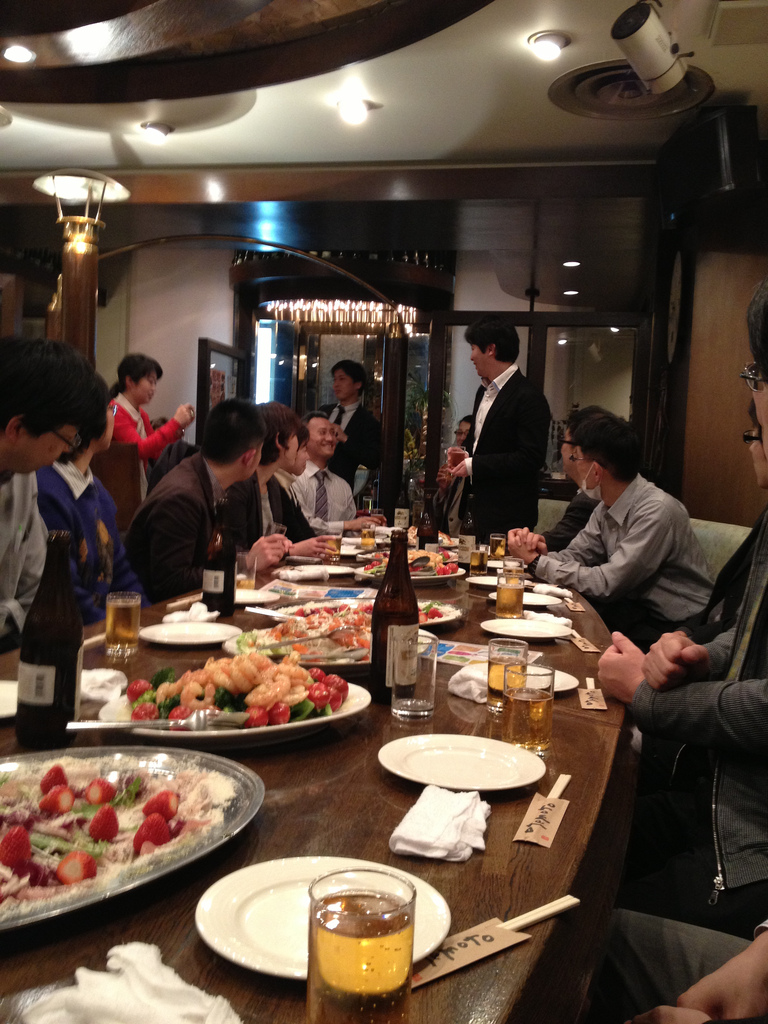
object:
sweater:
[97, 392, 187, 527]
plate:
[376, 726, 556, 795]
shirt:
[533, 474, 717, 629]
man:
[495, 411, 723, 646]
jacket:
[456, 367, 551, 539]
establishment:
[32, 203, 744, 997]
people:
[0, 319, 150, 658]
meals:
[0, 578, 459, 926]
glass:
[392, 502, 410, 530]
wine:
[366, 521, 426, 703]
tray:
[9, 736, 265, 950]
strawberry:
[39, 777, 70, 819]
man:
[450, 307, 546, 526]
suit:
[453, 381, 565, 540]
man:
[315, 355, 384, 491]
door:
[234, 247, 434, 494]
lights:
[318, 59, 392, 131]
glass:
[303, 856, 417, 1019]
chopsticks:
[403, 885, 581, 998]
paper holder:
[411, 912, 532, 987]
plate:
[192, 842, 454, 989]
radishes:
[130, 812, 183, 854]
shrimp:
[132, 641, 371, 743]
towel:
[374, 786, 494, 862]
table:
[0, 512, 629, 1023]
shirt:
[95, 395, 172, 508]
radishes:
[55, 842, 97, 874]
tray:
[98, 614, 366, 742]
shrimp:
[183, 655, 311, 690]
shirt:
[37, 458, 142, 626]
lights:
[506, 19, 582, 88]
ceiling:
[0, 0, 768, 204]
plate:
[376, 728, 549, 791]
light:
[30, 167, 136, 258]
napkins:
[386, 783, 492, 866]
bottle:
[367, 525, 420, 712]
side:
[51, 430, 76, 454]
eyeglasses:
[51, 427, 84, 452]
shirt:
[533, 469, 715, 622]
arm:
[113, 397, 195, 463]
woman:
[97, 347, 193, 541]